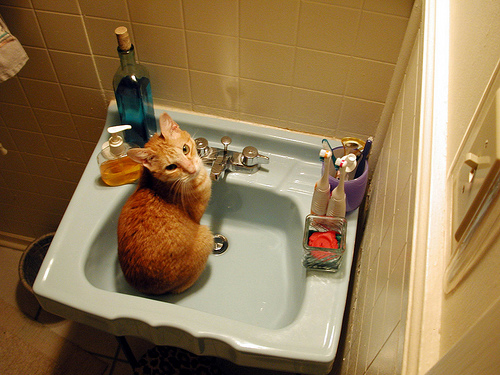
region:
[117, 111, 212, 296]
blonde tabby cat sitting inside a bathroom sink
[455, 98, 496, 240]
cream colored light switch on a wall inside a bathroom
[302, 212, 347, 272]
red candle inside a square shaped holder made of thick glass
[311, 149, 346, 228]
pair of electric toothbrushes standing upright on a sink ledge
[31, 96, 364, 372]
very pale blue sink inside a bathroom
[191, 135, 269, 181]
silver colored bathroom sink fixtures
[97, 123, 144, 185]
pump bottle half filled with a golden colored liquid soap resting on a bathroom sink ledge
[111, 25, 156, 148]
decorative bottle tinted blue with a cork resting on a sink ledge in a bathroom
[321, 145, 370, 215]
purple cup filled with toiletries inside a bathroom on a sink ledge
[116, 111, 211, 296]
light orange tabby cat sitting in the base of a bathroom sink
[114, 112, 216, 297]
Orange cat sitting in bathroom sink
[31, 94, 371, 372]
White porcelain bathroom sink in corner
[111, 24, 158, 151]
Blue glass bottle with cork in top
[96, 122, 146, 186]
Pump soap dispenser containing yellow liquid soap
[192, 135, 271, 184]
Silver faucet and plug assembly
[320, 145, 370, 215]
Purple cup holding toothbrushes and tube of toothpaste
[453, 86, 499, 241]
Beige light switch on wall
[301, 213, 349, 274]
Clear glass candle holder with red candle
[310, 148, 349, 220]
Pair of electric toothbrushes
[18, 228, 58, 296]
Trash basket on floor beside sink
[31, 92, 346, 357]
A light blue bathroom sink.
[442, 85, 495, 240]
A light switch on the right wall.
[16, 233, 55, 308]
Partial view of the waste paper bin.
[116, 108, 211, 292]
An orange cat sitting in the bathroom sink.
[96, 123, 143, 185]
Liquid soap in a pump bottle.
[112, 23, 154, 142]
A long blue bottle with a cork stopper.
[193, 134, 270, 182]
The sink fixtures.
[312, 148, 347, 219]
Battery operated toothbrushes.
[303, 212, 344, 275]
Red candle in candle holder.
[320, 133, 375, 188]
Toothpaste and brushes in a holder.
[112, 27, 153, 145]
blue vase with a cork in it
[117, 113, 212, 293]
orange house cat in the sink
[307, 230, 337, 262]
red candle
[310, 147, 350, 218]
two electric toothbrushes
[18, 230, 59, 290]
wicker trash can on the ground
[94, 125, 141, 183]
the soap dispenser is on the sink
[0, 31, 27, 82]
end of a white towel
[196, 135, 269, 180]
silver water faucet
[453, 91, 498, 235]
the light switch is on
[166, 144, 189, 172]
cat has green eyes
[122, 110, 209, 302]
The cat inside of the sink.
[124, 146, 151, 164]
The left ear of the cat.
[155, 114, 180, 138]
The right ear of the cat.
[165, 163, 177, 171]
The left eye of the cat.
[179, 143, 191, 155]
The right eye of the cat.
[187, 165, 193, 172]
The nose of the cat.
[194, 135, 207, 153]
The left knob on the sink.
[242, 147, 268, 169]
The right knob on the sink.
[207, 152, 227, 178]
The faucet of the sink.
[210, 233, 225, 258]
The drain hole inside of the sink.